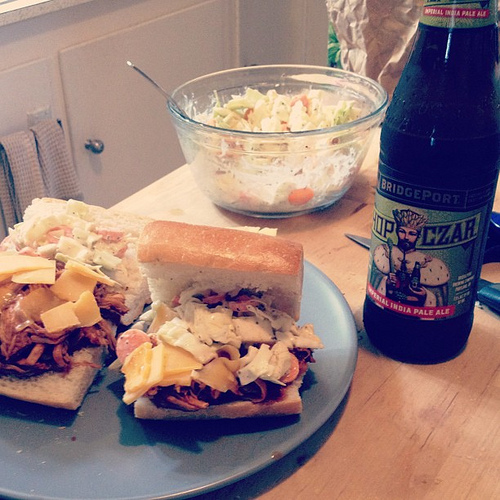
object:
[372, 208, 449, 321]
image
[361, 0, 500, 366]
beer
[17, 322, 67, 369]
meat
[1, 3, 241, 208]
cabinet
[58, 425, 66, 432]
crumb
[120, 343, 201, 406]
cheddar cheese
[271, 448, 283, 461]
brown spot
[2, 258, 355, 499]
plate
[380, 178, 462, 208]
bridgeport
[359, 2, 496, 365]
bottle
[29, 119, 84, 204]
kitchen towel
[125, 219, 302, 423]
sandwich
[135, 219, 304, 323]
bread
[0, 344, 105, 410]
bread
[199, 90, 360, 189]
cole slaw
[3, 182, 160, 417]
sandwich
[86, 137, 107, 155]
door knob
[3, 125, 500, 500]
table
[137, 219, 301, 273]
crust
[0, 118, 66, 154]
rack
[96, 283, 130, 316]
meat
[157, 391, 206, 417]
meat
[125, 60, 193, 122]
spoon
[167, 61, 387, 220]
bowl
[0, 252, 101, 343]
cheese